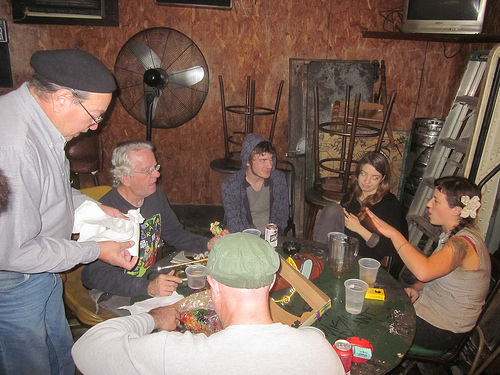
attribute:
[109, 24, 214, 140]
fan — black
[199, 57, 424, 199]
stools — upside down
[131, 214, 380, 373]
table — green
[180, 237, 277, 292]
hat — green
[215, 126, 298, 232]
jacket — gray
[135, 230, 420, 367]
table — round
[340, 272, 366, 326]
glass — clear, plastic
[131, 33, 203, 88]
blades — silver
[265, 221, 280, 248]
can — aluminum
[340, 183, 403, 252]
shirt — black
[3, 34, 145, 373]
man — standing